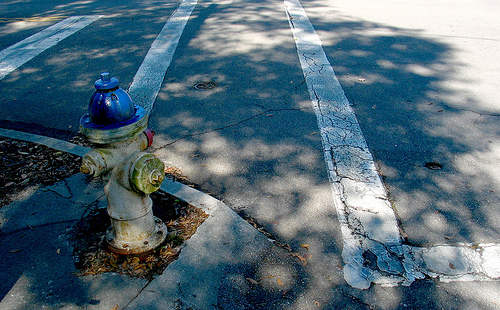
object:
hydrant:
[70, 69, 173, 260]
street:
[0, 1, 498, 310]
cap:
[73, 70, 152, 134]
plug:
[144, 127, 155, 149]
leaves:
[125, 254, 147, 270]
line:
[284, 1, 401, 289]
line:
[128, 1, 198, 112]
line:
[1, 3, 100, 78]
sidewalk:
[1, 157, 250, 309]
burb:
[1, 128, 83, 156]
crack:
[150, 107, 313, 155]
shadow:
[0, 0, 500, 310]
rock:
[20, 173, 29, 179]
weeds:
[382, 175, 396, 209]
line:
[335, 241, 500, 288]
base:
[99, 210, 171, 256]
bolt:
[142, 240, 149, 245]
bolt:
[156, 230, 164, 235]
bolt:
[106, 236, 115, 243]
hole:
[421, 159, 447, 171]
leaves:
[32, 153, 55, 168]